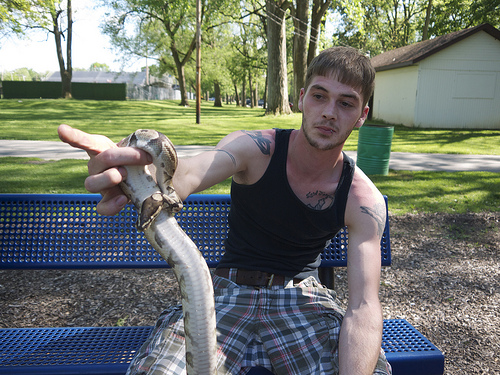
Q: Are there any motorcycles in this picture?
A: No, there are no motorcycles.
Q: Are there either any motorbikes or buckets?
A: No, there are no motorbikes or buckets.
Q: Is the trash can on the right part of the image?
A: Yes, the trash can is on the right of the image.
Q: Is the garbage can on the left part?
A: No, the garbage can is on the right of the image.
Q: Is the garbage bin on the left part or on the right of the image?
A: The garbage bin is on the right of the image.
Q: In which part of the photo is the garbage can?
A: The garbage can is on the right of the image.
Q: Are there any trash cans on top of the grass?
A: Yes, there is a trash can on top of the grass.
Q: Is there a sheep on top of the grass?
A: No, there is a trash can on top of the grass.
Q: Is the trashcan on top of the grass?
A: Yes, the trashcan is on top of the grass.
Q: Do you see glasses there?
A: No, there are no glasses.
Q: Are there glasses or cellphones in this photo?
A: No, there are no glasses or cellphones.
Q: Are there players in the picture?
A: No, there are no players.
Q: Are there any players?
A: No, there are no players.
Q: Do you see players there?
A: No, there are no players.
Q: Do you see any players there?
A: No, there are no players.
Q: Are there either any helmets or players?
A: No, there are no players or helmets.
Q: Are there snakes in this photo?
A: Yes, there is a snake.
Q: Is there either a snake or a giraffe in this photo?
A: Yes, there is a snake.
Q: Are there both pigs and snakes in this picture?
A: No, there is a snake but no pigs.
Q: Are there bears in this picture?
A: No, there are no bears.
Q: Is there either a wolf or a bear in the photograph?
A: No, there are no bears or wolves.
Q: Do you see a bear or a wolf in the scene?
A: No, there are no bears or wolves.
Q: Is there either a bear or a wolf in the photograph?
A: No, there are no bears or wolves.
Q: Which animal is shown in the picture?
A: The animal is a snake.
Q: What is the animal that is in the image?
A: The animal is a snake.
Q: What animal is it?
A: The animal is a snake.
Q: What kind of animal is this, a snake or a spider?
A: This is a snake.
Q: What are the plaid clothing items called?
A: The clothing items are shorts.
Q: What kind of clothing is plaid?
A: The clothing is shorts.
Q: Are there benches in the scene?
A: Yes, there is a bench.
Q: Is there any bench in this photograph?
A: Yes, there is a bench.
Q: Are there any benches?
A: Yes, there is a bench.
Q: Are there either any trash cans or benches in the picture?
A: Yes, there is a bench.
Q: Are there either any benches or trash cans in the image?
A: Yes, there is a bench.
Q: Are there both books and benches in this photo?
A: No, there is a bench but no books.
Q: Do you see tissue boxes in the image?
A: No, there are no tissue boxes.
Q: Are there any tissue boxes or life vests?
A: No, there are no tissue boxes or life vests.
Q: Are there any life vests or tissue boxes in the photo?
A: No, there are no tissue boxes or life vests.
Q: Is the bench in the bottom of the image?
A: Yes, the bench is in the bottom of the image.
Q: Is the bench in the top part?
A: No, the bench is in the bottom of the image.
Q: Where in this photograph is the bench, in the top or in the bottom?
A: The bench is in the bottom of the image.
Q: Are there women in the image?
A: No, there are no women.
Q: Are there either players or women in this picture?
A: No, there are no women or players.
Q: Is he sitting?
A: Yes, the man is sitting.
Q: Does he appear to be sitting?
A: Yes, the man is sitting.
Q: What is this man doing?
A: The man is sitting.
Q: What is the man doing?
A: The man is sitting.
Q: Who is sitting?
A: The man is sitting.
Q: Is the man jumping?
A: No, the man is sitting.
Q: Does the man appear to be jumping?
A: No, the man is sitting.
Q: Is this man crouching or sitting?
A: The man is sitting.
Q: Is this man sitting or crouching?
A: The man is sitting.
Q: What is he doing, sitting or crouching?
A: The man is sitting.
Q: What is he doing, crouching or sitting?
A: The man is sitting.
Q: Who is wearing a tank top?
A: The man is wearing a tank top.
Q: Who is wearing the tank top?
A: The man is wearing a tank top.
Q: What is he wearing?
A: The man is wearing a tank top.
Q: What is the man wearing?
A: The man is wearing a tank top.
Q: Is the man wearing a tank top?
A: Yes, the man is wearing a tank top.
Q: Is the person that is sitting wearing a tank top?
A: Yes, the man is wearing a tank top.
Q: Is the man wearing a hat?
A: No, the man is wearing a tank top.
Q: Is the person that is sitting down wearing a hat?
A: No, the man is wearing a tank top.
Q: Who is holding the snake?
A: The man is holding the snake.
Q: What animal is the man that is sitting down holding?
A: The man is holding the snake.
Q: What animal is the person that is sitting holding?
A: The man is holding the snake.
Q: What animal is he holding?
A: The man is holding the snake.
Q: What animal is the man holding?
A: The man is holding the snake.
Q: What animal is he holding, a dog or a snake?
A: The man is holding a snake.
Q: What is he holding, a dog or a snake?
A: The man is holding a snake.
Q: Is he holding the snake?
A: Yes, the man is holding the snake.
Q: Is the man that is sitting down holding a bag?
A: No, the man is holding the snake.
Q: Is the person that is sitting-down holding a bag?
A: No, the man is holding the snake.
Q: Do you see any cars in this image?
A: No, there are no cars.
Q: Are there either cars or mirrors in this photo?
A: No, there are no cars or mirrors.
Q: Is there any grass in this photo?
A: Yes, there is grass.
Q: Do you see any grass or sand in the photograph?
A: Yes, there is grass.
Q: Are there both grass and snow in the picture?
A: No, there is grass but no snow.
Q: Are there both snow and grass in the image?
A: No, there is grass but no snow.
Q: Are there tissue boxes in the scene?
A: No, there are no tissue boxes.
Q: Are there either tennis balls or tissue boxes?
A: No, there are no tissue boxes or tennis balls.